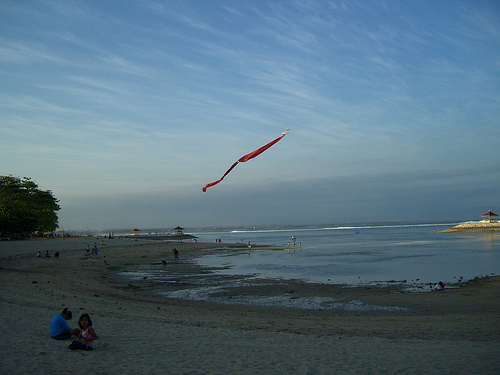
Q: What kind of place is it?
A: It is a beach.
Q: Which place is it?
A: It is a beach.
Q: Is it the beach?
A: Yes, it is the beach.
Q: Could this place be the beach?
A: Yes, it is the beach.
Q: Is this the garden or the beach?
A: It is the beach.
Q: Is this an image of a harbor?
A: No, the picture is showing a beach.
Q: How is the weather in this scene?
A: It is clear.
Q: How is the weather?
A: It is clear.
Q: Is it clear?
A: Yes, it is clear.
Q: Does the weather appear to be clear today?
A: Yes, it is clear.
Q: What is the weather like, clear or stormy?
A: It is clear.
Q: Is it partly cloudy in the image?
A: No, it is clear.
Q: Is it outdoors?
A: Yes, it is outdoors.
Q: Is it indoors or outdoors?
A: It is outdoors.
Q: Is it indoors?
A: No, it is outdoors.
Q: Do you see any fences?
A: No, there are no fences.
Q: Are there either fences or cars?
A: No, there are no fences or cars.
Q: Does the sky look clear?
A: Yes, the sky is clear.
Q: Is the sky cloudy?
A: No, the sky is clear.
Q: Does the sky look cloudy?
A: No, the sky is clear.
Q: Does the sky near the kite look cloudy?
A: No, the sky is clear.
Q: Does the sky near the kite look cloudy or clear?
A: The sky is clear.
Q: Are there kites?
A: Yes, there is a kite.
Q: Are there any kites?
A: Yes, there is a kite.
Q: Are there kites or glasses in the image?
A: Yes, there is a kite.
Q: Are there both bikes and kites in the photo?
A: No, there is a kite but no bikes.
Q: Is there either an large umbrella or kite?
A: Yes, there is a large kite.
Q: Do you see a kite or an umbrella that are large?
A: Yes, the kite is large.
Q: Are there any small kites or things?
A: Yes, there is a small kite.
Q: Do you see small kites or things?
A: Yes, there is a small kite.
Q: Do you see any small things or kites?
A: Yes, there is a small kite.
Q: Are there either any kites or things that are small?
A: Yes, the kite is small.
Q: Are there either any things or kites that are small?
A: Yes, the kite is small.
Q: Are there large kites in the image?
A: Yes, there is a large kite.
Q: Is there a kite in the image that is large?
A: Yes, there is a kite that is large.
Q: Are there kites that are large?
A: Yes, there is a kite that is large.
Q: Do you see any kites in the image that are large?
A: Yes, there is a kite that is large.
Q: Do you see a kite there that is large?
A: Yes, there is a kite that is large.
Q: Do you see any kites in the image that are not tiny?
A: Yes, there is a large kite.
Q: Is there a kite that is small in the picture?
A: Yes, there is a small kite.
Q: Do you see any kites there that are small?
A: Yes, there is a kite that is small.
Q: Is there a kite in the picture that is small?
A: Yes, there is a kite that is small.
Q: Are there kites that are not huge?
A: Yes, there is a small kite.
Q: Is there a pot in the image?
A: No, there are no pots.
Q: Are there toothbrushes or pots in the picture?
A: No, there are no pots or toothbrushes.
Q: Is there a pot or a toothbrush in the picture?
A: No, there are no pots or toothbrushes.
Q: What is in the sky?
A: The kite is in the sky.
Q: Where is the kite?
A: The kite is in the sky.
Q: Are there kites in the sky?
A: Yes, there is a kite in the sky.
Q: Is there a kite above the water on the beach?
A: Yes, there is a kite above the water.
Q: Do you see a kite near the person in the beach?
A: Yes, there is a kite near the person.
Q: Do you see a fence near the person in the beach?
A: No, there is a kite near the person.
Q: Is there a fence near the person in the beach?
A: No, there is a kite near the person.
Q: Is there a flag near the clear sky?
A: No, there is a kite near the sky.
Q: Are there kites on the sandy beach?
A: Yes, there is a kite on the beach.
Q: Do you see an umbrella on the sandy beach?
A: No, there is a kite on the beach.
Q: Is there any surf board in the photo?
A: No, there are no surfboards.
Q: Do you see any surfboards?
A: No, there are no surfboards.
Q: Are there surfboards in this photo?
A: No, there are no surfboards.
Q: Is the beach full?
A: Yes, the beach is full.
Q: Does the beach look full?
A: Yes, the beach is full.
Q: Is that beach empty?
A: No, the beach is full.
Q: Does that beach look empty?
A: No, the beach is full.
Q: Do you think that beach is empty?
A: No, the beach is full.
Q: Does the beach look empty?
A: No, the beach is full.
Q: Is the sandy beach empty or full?
A: The beach is full.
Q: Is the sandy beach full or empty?
A: The beach is full.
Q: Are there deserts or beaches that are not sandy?
A: No, there is a beach but it is sandy.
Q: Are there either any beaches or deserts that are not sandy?
A: No, there is a beach but it is sandy.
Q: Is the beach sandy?
A: Yes, the beach is sandy.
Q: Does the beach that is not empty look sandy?
A: Yes, the beach is sandy.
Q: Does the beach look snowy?
A: No, the beach is sandy.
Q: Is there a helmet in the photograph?
A: No, there are no helmets.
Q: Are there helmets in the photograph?
A: No, there are no helmets.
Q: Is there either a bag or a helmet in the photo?
A: No, there are no helmets or bags.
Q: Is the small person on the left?
A: Yes, the person is on the left of the image.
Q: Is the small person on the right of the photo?
A: No, the person is on the left of the image.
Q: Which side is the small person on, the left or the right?
A: The person is on the left of the image.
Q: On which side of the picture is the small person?
A: The person is on the left of the image.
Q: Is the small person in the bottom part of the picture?
A: Yes, the person is in the bottom of the image.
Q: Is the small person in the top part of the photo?
A: No, the person is in the bottom of the image.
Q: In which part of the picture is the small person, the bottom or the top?
A: The person is in the bottom of the image.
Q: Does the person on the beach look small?
A: Yes, the person is small.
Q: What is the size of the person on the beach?
A: The person is small.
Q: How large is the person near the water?
A: The person is small.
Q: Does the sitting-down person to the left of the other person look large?
A: No, the person is small.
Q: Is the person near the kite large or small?
A: The person is small.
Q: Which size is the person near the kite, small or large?
A: The person is small.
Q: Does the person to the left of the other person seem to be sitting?
A: Yes, the person is sitting.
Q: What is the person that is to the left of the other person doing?
A: The person is sitting.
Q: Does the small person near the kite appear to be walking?
A: No, the person is sitting.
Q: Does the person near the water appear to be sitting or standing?
A: The person is sitting.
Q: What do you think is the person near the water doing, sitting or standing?
A: The person is sitting.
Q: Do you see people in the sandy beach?
A: Yes, there is a person in the beach.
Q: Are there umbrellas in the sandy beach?
A: No, there is a person in the beach.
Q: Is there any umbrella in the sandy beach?
A: No, there is a person in the beach.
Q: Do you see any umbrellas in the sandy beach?
A: No, there is a person in the beach.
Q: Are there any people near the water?
A: Yes, there is a person near the water.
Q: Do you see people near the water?
A: Yes, there is a person near the water.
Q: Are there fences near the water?
A: No, there is a person near the water.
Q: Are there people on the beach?
A: Yes, there is a person on the beach.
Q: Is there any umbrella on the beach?
A: No, there is a person on the beach.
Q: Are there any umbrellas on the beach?
A: No, there is a person on the beach.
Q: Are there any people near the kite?
A: Yes, there is a person near the kite.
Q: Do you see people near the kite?
A: Yes, there is a person near the kite.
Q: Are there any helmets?
A: No, there are no helmets.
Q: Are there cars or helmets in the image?
A: No, there are no helmets or cars.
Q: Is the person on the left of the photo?
A: Yes, the person is on the left of the image.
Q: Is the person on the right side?
A: No, the person is on the left of the image.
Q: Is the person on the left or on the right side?
A: The person is on the left of the image.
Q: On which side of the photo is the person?
A: The person is on the left of the image.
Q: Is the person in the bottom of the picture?
A: Yes, the person is in the bottom of the image.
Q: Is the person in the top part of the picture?
A: No, the person is in the bottom of the image.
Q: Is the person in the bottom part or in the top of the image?
A: The person is in the bottom of the image.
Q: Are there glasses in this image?
A: No, there are no glasses.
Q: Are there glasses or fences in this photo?
A: No, there are no glasses or fences.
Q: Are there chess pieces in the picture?
A: No, there are no chess pieces.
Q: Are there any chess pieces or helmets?
A: No, there are no chess pieces or helmets.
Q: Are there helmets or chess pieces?
A: No, there are no chess pieces or helmets.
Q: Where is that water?
A: The water is on the beach.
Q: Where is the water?
A: The water is on the beach.